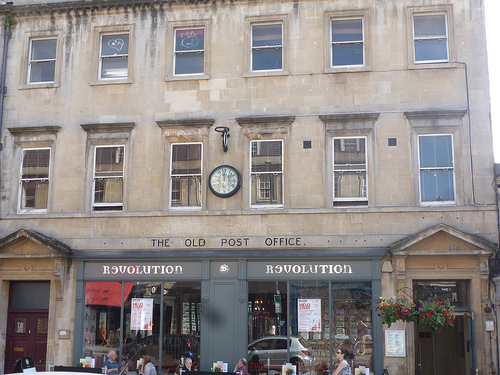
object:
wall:
[192, 78, 274, 116]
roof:
[0, 0, 146, 21]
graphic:
[130, 296, 154, 331]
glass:
[249, 50, 281, 70]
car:
[247, 335, 317, 372]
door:
[104, 308, 165, 366]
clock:
[208, 164, 242, 198]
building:
[1, 0, 499, 374]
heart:
[108, 37, 126, 53]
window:
[250, 22, 287, 74]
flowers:
[417, 300, 456, 328]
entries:
[85, 260, 295, 372]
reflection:
[250, 276, 298, 348]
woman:
[327, 345, 351, 375]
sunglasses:
[337, 349, 343, 355]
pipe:
[214, 126, 232, 154]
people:
[102, 346, 358, 375]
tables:
[219, 364, 279, 372]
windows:
[25, 14, 450, 83]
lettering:
[149, 234, 304, 248]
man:
[178, 356, 200, 374]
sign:
[100, 67, 131, 83]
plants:
[363, 297, 418, 330]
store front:
[72, 237, 387, 375]